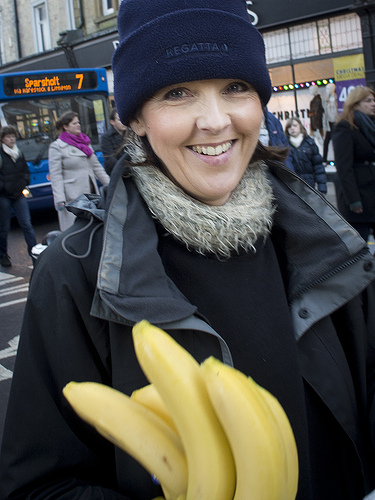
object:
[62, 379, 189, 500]
banana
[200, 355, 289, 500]
banana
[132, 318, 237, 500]
banana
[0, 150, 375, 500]
jacket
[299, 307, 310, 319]
button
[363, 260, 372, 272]
button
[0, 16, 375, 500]
woman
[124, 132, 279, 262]
scarf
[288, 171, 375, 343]
zipper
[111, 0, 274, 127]
cap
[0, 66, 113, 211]
bus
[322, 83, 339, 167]
mannequin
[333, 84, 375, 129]
hair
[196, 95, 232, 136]
nose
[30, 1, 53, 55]
window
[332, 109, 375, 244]
coat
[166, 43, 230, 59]
writing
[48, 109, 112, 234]
woman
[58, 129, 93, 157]
scarf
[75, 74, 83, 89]
numbers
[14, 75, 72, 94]
writing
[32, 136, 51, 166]
windshield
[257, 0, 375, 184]
building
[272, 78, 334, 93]
lights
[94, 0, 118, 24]
window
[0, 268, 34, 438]
street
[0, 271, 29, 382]
paint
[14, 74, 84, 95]
lighted route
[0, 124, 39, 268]
people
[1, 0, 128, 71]
building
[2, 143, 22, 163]
scarf